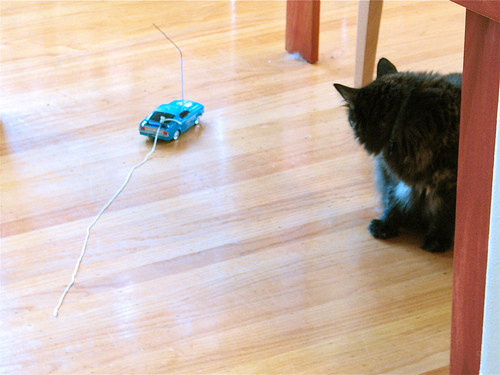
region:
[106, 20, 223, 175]
a small toy car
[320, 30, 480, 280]
a cat on the wooden floor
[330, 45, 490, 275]
a cat sitting under a table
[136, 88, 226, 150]
a blue toy car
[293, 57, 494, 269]
a cat looking at a toy car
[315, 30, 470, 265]
a furry black cat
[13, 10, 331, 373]
a toy car on the light wood floor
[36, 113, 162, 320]
a string tied to a toy car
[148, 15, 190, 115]
an antenna of a remote control car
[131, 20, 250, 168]
a toy remote control car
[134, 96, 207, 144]
small blue toy car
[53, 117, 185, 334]
white string attached to car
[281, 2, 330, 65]
bottom of table leg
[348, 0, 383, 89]
bottom of chair leg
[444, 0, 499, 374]
part of table leg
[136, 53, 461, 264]
cat watching blue car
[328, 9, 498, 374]
black cat under table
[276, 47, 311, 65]
dust under table leg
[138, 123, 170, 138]
red tailights on toy car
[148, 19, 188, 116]
thing sticking up from car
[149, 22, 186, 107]
white car antenna of car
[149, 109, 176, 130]
small black rear window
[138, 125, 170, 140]
two small back red lights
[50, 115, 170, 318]
white rope tied to a car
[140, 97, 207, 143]
small light blue toy car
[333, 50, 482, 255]
black furry cat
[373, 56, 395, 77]
small black furry right ear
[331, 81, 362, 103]
small black furry left ear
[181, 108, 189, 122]
small black right window of toy car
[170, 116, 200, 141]
two right wheels of toy car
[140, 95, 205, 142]
a small blue toy car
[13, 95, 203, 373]
a blue toy car tied to a white string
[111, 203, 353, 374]
a patch of light wooded floor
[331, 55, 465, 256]
a big fluffy dark colored cat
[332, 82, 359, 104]
the left ear of a cat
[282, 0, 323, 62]
the bottom of light wooden table leg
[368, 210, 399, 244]
a cats front paw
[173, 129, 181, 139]
the back tire of a toy car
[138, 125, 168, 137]
the back red tail lights of a toy car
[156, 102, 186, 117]
the roof of a blue toy car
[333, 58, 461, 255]
A fluffy black cat.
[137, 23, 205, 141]
A light blue toy car.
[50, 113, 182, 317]
A white string attached to a truck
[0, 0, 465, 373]
A light brown wooden floor.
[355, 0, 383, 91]
A leg of a chair.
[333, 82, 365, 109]
An ear of a cat.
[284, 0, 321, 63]
A leg of a table.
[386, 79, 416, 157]
A collar around cat's neck.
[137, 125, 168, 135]
tail lights on toy car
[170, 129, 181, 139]
Wheel on toy car